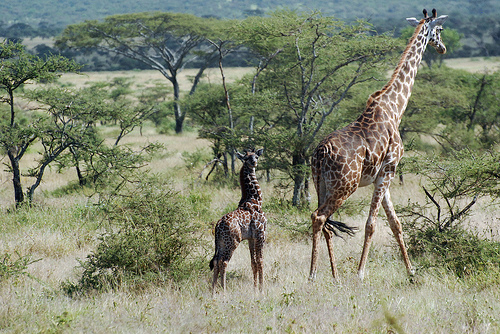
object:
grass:
[0, 56, 500, 334]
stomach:
[357, 170, 378, 186]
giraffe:
[308, 7, 447, 288]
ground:
[2, 56, 498, 334]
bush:
[60, 180, 213, 299]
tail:
[315, 148, 361, 239]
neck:
[378, 30, 431, 111]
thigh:
[368, 166, 395, 215]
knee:
[389, 217, 403, 235]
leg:
[358, 157, 396, 274]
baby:
[212, 166, 267, 298]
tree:
[55, 12, 258, 134]